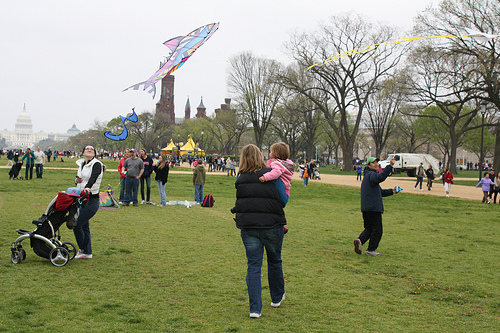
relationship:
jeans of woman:
[239, 220, 286, 315] [228, 140, 287, 320]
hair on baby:
[268, 138, 289, 160] [258, 141, 295, 238]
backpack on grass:
[199, 191, 217, 209] [114, 211, 224, 316]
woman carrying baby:
[232, 142, 293, 317] [261, 136, 306, 201]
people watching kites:
[118, 147, 169, 207] [105, 20, 220, 143]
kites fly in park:
[105, 20, 220, 143] [2, 150, 494, 327]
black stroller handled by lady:
[10, 191, 90, 273] [67, 143, 106, 260]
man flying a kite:
[354, 142, 407, 266] [104, 18, 226, 108]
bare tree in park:
[297, 21, 362, 176] [0, 143, 480, 310]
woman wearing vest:
[222, 131, 302, 325] [228, 168, 290, 233]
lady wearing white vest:
[71, 143, 107, 260] [73, 158, 104, 195]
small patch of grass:
[142, 270, 170, 302] [9, 272, 496, 331]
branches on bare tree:
[341, 63, 370, 95] [268, 21, 405, 172]